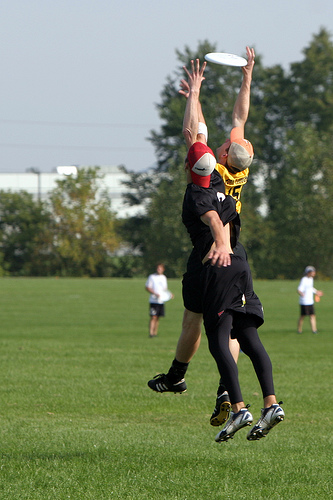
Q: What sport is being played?
A: Frisbee.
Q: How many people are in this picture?
A: 4.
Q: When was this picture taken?
A: Daytime.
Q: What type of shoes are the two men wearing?
A: Cleats.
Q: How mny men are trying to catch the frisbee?
A: 2.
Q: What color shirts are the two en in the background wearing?
A: White.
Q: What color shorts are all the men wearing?
A: Black.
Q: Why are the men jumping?
A: To catch frisbee.